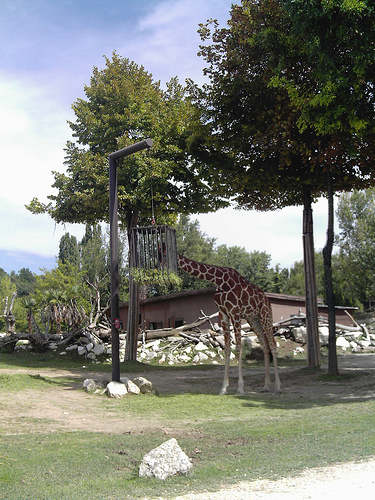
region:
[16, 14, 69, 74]
Sky is blue color.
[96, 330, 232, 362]
Rocks are grey color.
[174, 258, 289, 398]
Giraffe is eating.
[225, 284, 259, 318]
Spots are brown color.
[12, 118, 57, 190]
Clouds are white color.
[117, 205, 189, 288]
Feeding tray is hanging.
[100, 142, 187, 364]
Pole is grey color.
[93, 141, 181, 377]
feeding tray is hanging from the pole.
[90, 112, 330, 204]
leaves are green color.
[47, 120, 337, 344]
trees are behind the giraffe.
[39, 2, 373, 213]
two green leafy trees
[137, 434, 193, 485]
a white rock on the ground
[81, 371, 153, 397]
some rocks on the ground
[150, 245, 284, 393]
a little giraffe eating food out of a box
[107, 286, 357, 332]
a building behind the rocks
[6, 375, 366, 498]
a bunch of grass on the ground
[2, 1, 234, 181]
the blue sky with the white clouds on him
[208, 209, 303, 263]
another white cloud in the sky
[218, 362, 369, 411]
a shadow on the ground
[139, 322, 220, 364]
a little hill with a branch and rocks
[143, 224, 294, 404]
giraffes standing on the grass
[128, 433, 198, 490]
small boulder in the grass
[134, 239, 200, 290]
head stuck in the feeder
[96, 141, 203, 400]
tall feeder for the giraffe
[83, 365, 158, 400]
rocks around the pole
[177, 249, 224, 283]
long spotted neck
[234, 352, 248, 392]
bottom half of the leg has no spots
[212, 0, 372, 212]
thick dark green tree top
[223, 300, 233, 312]
dark brown spot on the skin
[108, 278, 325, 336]
brown building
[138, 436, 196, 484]
white rock all alone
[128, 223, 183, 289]
wooden cage hanging from a rope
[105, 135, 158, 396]
tall metal pole in the ground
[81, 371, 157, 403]
circle of white rocks around the metal pole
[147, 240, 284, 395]
tall giraffe with brown spots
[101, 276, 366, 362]
brown building behind giraffe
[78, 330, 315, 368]
lots of white rocks behind giraffe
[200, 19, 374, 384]
very tall and large tree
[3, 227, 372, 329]
lots of trees in the distance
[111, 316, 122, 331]
small red item attached to the pole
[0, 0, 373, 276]
The sky is blue.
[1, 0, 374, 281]
The sky is clear.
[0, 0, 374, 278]
The sky has a few clouds in it.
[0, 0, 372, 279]
The clouds are white.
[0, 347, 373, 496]
The grass is green.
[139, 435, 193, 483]
Rocks are on the ground.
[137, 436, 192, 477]
The rock is white.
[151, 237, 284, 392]
The giraffe is tall.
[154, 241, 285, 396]
The giraffe is brown and white.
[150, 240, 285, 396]
The giraffe has brown spots.